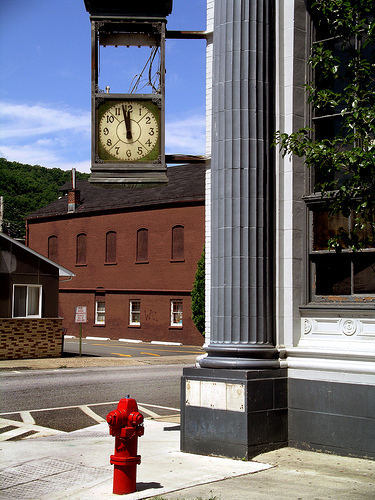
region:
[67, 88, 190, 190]
Clock mounted from side of building.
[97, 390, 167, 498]
Red fire hydrant on sidewalk.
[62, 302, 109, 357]
Traffic sign on sidewalk.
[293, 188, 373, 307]
Window of a building.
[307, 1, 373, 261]
Green foliage on side of building.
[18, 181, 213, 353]
Brown building on street.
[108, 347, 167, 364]
Yellow arrow signs on road.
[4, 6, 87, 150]
Blue sky with white clouds.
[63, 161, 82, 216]
Chimney of a building.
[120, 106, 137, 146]
Black hands of a clock.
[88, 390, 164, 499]
Red fire hydrant.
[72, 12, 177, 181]
Clock hanging from a building.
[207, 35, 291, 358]
Doric column supporting a building.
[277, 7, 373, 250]
Tree branches in front of a window.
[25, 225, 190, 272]
Brick building with sealed off windows.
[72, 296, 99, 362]
Parking sign on a street.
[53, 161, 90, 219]
Small chimney on a roof.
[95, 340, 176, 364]
Yellow traffic markings on a road.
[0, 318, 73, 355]
Patterned brown and red bricks.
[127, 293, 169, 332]
Graffiti on a wall.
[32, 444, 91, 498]
Metal plate on ground.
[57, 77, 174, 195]
Green and white clock.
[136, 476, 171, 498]
Shadow on the ground.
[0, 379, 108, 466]
White paint on the street.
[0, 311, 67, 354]
Tan and brown building.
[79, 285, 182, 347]
Three windows on side of building.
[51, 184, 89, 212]
Chimney on top of building.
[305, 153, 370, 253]
Green plant hanging from building.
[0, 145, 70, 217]
Lots of green tree tops.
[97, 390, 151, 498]
Red fire hydrant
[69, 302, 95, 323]
White street sign with red letters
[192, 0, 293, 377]
Large grey column on the side of a building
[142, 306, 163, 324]
Black graffiti on a red brick wall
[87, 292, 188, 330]
Three barred windows with white frames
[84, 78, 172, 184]
Clock with a green and cream face and two black hands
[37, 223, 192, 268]
Row of bricked shut windows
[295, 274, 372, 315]
Grey windowsill with peeling paint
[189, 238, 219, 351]
A tree on the other side of the building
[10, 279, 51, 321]
Simple white window with curtains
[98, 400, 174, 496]
a red fire hydrant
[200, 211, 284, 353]
a gray pillar on the building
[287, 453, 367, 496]
a portion of the sidewalk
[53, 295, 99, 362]
a white sign in the parking lot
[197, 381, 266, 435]
a white section of the base of the pillar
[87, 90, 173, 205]
a clock on the gray pillar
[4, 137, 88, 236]
a bunch of trees in the distance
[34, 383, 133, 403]
part of an asphalt street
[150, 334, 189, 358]
white concrete parking barrier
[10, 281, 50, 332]
a white framed window